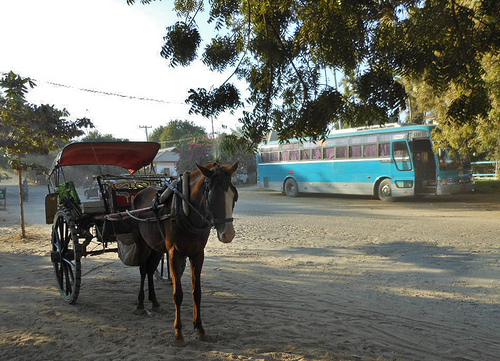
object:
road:
[0, 172, 499, 359]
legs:
[187, 252, 211, 343]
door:
[390, 138, 415, 198]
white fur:
[218, 187, 236, 237]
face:
[208, 186, 238, 244]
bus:
[256, 122, 476, 203]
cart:
[45, 141, 179, 304]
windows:
[261, 153, 270, 163]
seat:
[97, 175, 167, 215]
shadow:
[0, 178, 499, 229]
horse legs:
[168, 247, 186, 347]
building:
[153, 150, 181, 185]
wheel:
[50, 210, 82, 304]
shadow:
[1, 240, 498, 359]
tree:
[125, 0, 499, 156]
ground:
[1, 175, 498, 360]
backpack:
[54, 181, 84, 221]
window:
[393, 141, 409, 157]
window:
[362, 144, 377, 157]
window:
[336, 146, 347, 158]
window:
[311, 148, 322, 160]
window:
[289, 150, 300, 161]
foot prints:
[264, 314, 300, 324]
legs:
[133, 254, 154, 317]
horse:
[130, 162, 238, 346]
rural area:
[0, 0, 497, 361]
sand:
[0, 181, 499, 360]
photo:
[0, 0, 499, 360]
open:
[389, 138, 438, 199]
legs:
[147, 250, 167, 314]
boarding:
[390, 138, 416, 197]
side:
[349, 145, 363, 158]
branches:
[243, 62, 276, 154]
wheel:
[284, 178, 298, 198]